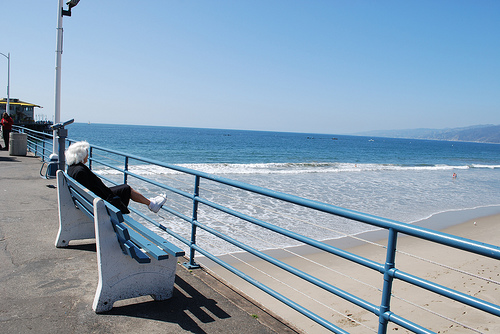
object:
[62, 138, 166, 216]
woman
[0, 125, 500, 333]
railing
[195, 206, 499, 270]
beach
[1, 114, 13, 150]
person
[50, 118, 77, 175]
telescope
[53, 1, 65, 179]
pole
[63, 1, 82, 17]
light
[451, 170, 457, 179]
someone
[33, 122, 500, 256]
ocean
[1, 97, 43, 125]
building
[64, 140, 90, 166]
hair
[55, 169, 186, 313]
bench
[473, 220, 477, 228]
sea gull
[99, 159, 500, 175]
waves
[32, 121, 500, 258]
water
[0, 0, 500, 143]
sky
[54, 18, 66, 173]
metal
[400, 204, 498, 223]
shore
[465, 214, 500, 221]
edge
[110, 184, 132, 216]
skirt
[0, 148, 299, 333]
floor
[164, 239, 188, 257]
edge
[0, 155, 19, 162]
shade